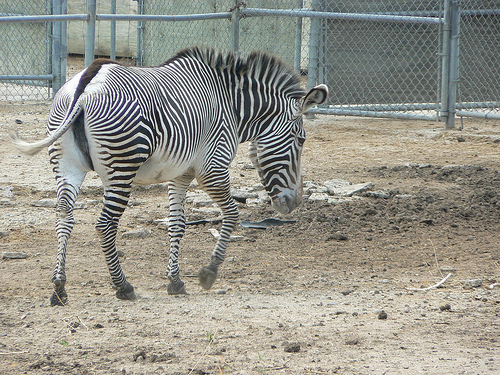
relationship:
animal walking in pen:
[10, 45, 329, 307] [2, 1, 483, 371]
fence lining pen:
[3, 0, 499, 137] [2, 1, 483, 371]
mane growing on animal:
[159, 46, 306, 101] [10, 45, 329, 307]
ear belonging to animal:
[301, 83, 329, 118] [10, 45, 329, 307]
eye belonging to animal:
[296, 137, 305, 144] [10, 45, 329, 307]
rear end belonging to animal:
[7, 56, 109, 157] [10, 45, 329, 307]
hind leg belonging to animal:
[92, 130, 155, 300] [10, 45, 329, 307]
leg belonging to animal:
[192, 161, 242, 266] [10, 45, 329, 307]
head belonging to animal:
[247, 90, 307, 215] [10, 45, 329, 307]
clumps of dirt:
[304, 210, 456, 263] [3, 87, 497, 373]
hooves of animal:
[162, 261, 224, 301] [10, 45, 329, 307]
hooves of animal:
[34, 277, 148, 314] [10, 45, 329, 307]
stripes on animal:
[131, 72, 229, 157] [10, 45, 329, 307]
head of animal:
[247, 81, 328, 215] [10, 45, 329, 307]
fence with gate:
[3, 0, 499, 137] [442, 5, 499, 133]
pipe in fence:
[6, 5, 473, 39] [3, 0, 498, 132]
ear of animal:
[297, 74, 337, 119] [10, 45, 329, 307]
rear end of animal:
[7, 56, 109, 157] [10, 45, 329, 307]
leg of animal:
[192, 161, 242, 266] [10, 45, 329, 307]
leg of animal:
[163, 180, 186, 297] [10, 45, 329, 307]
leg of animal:
[93, 163, 139, 287] [10, 45, 329, 307]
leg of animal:
[34, 152, 92, 318] [10, 45, 329, 307]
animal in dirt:
[10, 45, 329, 307] [3, 87, 497, 373]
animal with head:
[10, 45, 329, 307] [251, 54, 343, 220]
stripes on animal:
[167, 75, 234, 138] [10, 45, 329, 307]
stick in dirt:
[402, 268, 470, 304] [3, 87, 497, 373]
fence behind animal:
[3, 0, 498, 132] [10, 45, 329, 307]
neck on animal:
[213, 49, 297, 152] [10, 45, 329, 307]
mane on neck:
[159, 46, 306, 101] [213, 49, 297, 152]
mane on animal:
[159, 46, 306, 101] [10, 45, 329, 307]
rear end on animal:
[43, 60, 154, 180] [10, 45, 329, 307]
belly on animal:
[127, 152, 207, 192] [10, 45, 329, 307]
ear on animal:
[301, 83, 329, 118] [10, 45, 329, 307]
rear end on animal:
[7, 56, 109, 157] [10, 45, 329, 307]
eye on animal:
[296, 137, 305, 144] [10, 45, 329, 307]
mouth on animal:
[282, 193, 297, 210] [10, 45, 329, 307]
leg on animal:
[93, 166, 139, 300] [10, 45, 329, 307]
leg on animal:
[48, 146, 92, 277] [10, 45, 329, 307]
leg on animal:
[192, 161, 242, 266] [10, 45, 329, 307]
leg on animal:
[163, 180, 186, 297] [10, 45, 329, 307]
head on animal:
[247, 81, 328, 215] [10, 45, 329, 307]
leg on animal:
[93, 163, 139, 287] [10, 45, 329, 307]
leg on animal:
[192, 161, 241, 291] [10, 45, 329, 307]